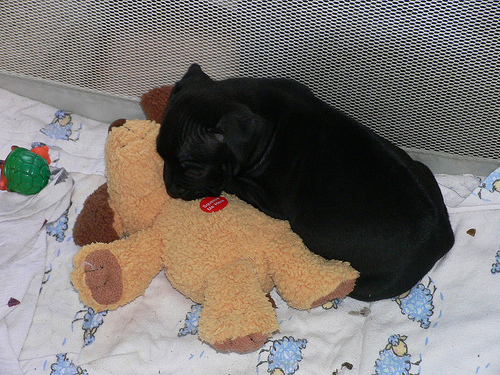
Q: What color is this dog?
A: Black.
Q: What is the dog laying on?
A: A doll.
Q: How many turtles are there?
A: 1.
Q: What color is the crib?
A: White.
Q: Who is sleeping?
A: The dog.